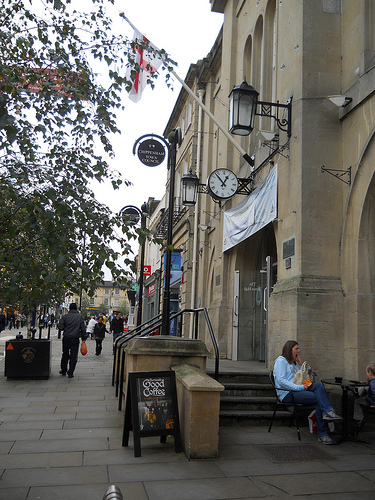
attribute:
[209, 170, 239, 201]
clock — white, numerals, round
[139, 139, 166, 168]
sign — metal, black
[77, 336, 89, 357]
bag — orange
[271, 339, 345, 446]
woman — sitting in chair, sitting, yawning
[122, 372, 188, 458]
sign — standing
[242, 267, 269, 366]
door — glass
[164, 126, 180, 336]
pole — black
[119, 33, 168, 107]
flag — white, flying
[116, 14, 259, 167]
pole — white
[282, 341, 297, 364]
hair — brown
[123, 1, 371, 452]
building — yellow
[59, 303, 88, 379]
person — walking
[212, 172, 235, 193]
face — white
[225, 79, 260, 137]
light — off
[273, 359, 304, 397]
sweater — blue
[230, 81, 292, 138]
lantern — mounted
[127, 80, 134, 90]
leaf — green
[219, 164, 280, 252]
banner — white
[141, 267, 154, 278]
sign — red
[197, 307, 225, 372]
handrail — black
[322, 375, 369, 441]
legs — crossed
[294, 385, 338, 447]
legs — crossed